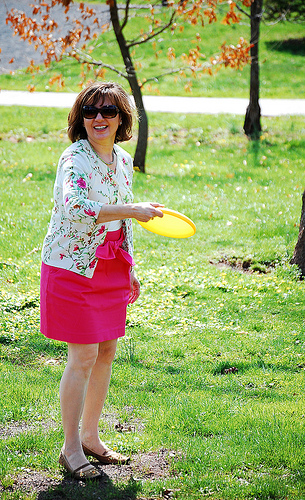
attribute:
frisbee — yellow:
[143, 197, 213, 270]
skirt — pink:
[41, 256, 136, 349]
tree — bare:
[99, 18, 187, 78]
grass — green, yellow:
[184, 268, 269, 346]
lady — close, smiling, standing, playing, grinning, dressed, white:
[33, 74, 195, 485]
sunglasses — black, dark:
[79, 105, 120, 120]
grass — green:
[213, 317, 269, 385]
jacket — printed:
[24, 138, 136, 271]